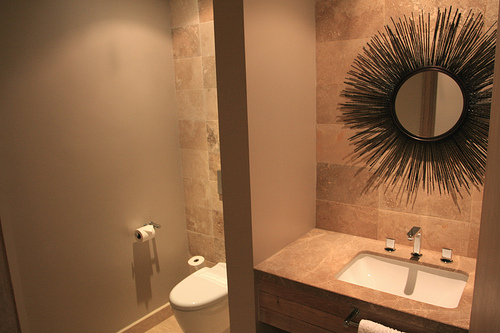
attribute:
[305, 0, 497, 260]
wall — tiled, marble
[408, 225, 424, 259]
faucet — silver, chrome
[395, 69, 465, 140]
mirror — circular, round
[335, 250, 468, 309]
sink — white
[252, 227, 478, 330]
counter — marble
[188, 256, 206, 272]
toilet paper roll — white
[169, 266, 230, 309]
lid — closed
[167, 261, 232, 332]
toilet — white, tankless, porcelain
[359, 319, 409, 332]
towel — white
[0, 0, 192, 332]
wall — beige, smooth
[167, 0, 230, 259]
tile — beige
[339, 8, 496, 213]
frame — metal